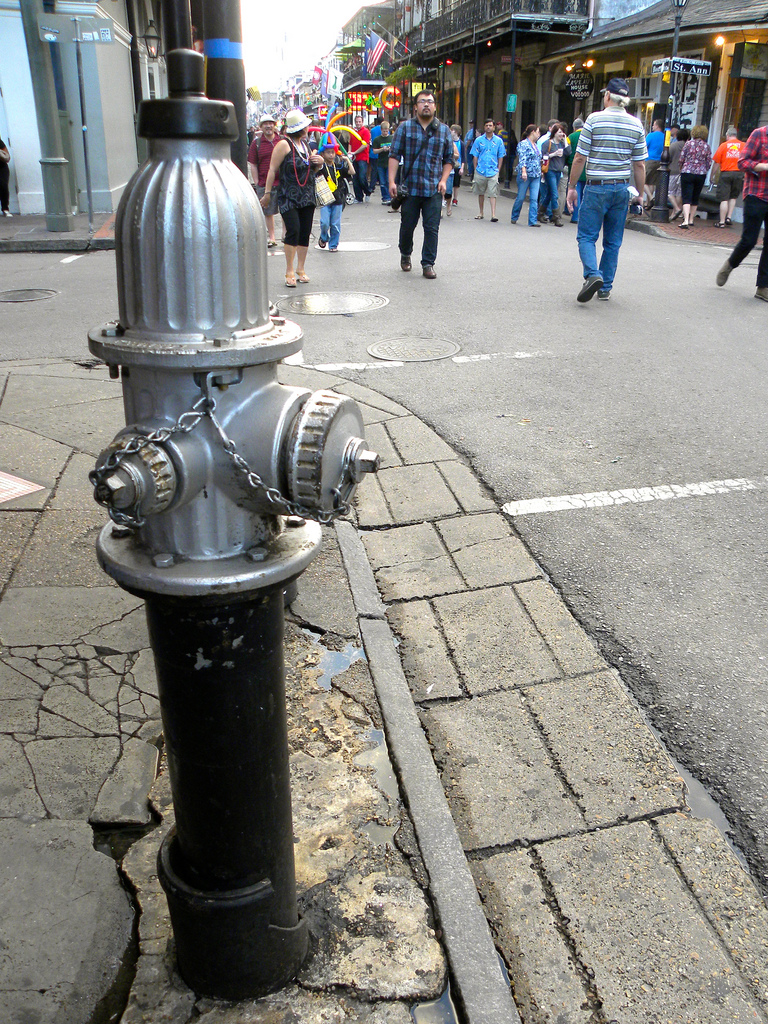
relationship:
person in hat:
[263, 99, 328, 294] [247, 92, 379, 156]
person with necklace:
[263, 99, 328, 294] [267, 127, 345, 180]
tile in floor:
[365, 533, 473, 607] [361, 498, 627, 929]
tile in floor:
[447, 504, 551, 591] [367, 469, 737, 896]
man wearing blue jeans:
[553, 76, 660, 318] [566, 171, 635, 288]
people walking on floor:
[243, 64, 733, 301] [0, 173, 767, 1023]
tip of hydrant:
[137, 46, 243, 139] [90, 39, 381, 1009]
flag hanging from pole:
[344, 22, 398, 83] [377, 41, 423, 63]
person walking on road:
[560, 67, 643, 314] [393, 160, 765, 685]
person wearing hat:
[263, 99, 328, 294] [279, 107, 308, 137]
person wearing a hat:
[263, 99, 328, 294] [252, 86, 320, 143]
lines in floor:
[526, 851, 626, 1014] [0, 173, 767, 1023]